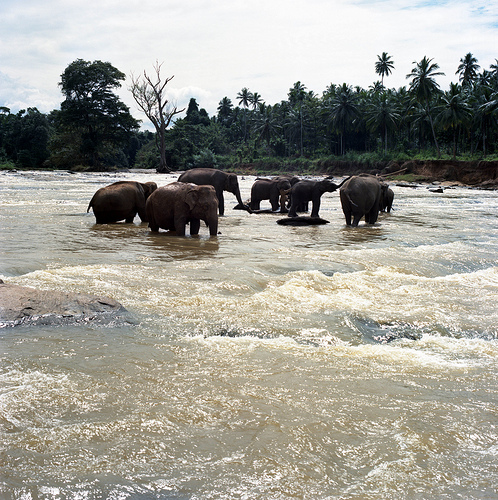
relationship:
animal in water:
[253, 169, 413, 230] [0, 171, 496, 498]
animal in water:
[338, 169, 395, 226] [0, 171, 496, 498]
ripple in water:
[48, 416, 154, 498] [0, 171, 496, 498]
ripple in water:
[127, 444, 257, 488] [0, 171, 496, 498]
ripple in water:
[230, 433, 326, 497] [0, 171, 496, 498]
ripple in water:
[356, 415, 418, 498] [0, 171, 496, 498]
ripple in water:
[4, 360, 98, 415] [0, 171, 496, 498]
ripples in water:
[111, 416, 172, 431] [0, 171, 496, 498]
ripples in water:
[0, 368, 102, 429] [0, 171, 496, 498]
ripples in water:
[392, 431, 438, 453] [0, 171, 496, 498]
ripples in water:
[46, 413, 169, 439] [0, 171, 496, 498]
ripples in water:
[191, 333, 300, 350] [0, 171, 496, 498]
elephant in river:
[178, 167, 246, 216] [0, 167, 495, 497]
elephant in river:
[87, 181, 158, 225] [0, 167, 495, 497]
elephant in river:
[146, 181, 224, 235] [0, 167, 495, 497]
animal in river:
[338, 176, 394, 226] [0, 167, 495, 497]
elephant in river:
[284, 175, 354, 218] [0, 167, 495, 497]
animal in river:
[338, 176, 394, 226] [222, 257, 443, 364]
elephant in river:
[146, 181, 224, 235] [222, 257, 443, 364]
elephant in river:
[87, 181, 158, 225] [222, 257, 443, 364]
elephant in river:
[178, 167, 246, 216] [222, 257, 443, 364]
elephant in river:
[284, 175, 354, 218] [222, 257, 443, 364]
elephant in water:
[87, 181, 158, 225] [57, 254, 471, 370]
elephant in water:
[146, 181, 224, 235] [0, 171, 496, 498]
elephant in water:
[178, 167, 246, 216] [0, 171, 496, 498]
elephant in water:
[87, 181, 158, 225] [0, 171, 496, 498]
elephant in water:
[284, 174, 352, 215] [0, 171, 496, 498]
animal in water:
[338, 176, 394, 226] [0, 171, 496, 498]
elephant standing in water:
[146, 181, 224, 235] [0, 171, 496, 498]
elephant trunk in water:
[203, 210, 221, 238] [0, 171, 496, 498]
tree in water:
[126, 58, 187, 175] [0, 171, 496, 498]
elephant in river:
[87, 181, 158, 225] [115, 270, 489, 417]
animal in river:
[248, 176, 292, 212] [0, 167, 495, 497]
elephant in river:
[146, 181, 224, 235] [93, 253, 445, 360]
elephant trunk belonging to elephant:
[205, 210, 218, 236] [146, 181, 224, 235]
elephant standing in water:
[87, 181, 158, 225] [0, 171, 496, 498]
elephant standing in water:
[178, 167, 246, 216] [0, 171, 496, 498]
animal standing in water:
[338, 176, 394, 226] [0, 171, 496, 498]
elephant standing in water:
[284, 175, 354, 218] [0, 171, 496, 498]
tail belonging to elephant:
[338, 185, 359, 213] [327, 162, 401, 233]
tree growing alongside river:
[124, 58, 186, 176] [0, 167, 495, 497]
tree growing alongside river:
[371, 49, 396, 89] [0, 167, 495, 497]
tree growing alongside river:
[287, 78, 307, 109] [0, 167, 495, 497]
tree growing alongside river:
[181, 95, 199, 121] [0, 167, 495, 497]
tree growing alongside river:
[235, 86, 256, 112] [0, 167, 495, 497]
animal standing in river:
[338, 176, 394, 226] [223, 239, 336, 282]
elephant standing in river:
[284, 175, 354, 218] [223, 239, 336, 282]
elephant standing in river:
[141, 185, 224, 236] [223, 239, 336, 282]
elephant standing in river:
[89, 175, 158, 237] [223, 239, 336, 282]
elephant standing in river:
[183, 165, 232, 192] [223, 239, 336, 282]